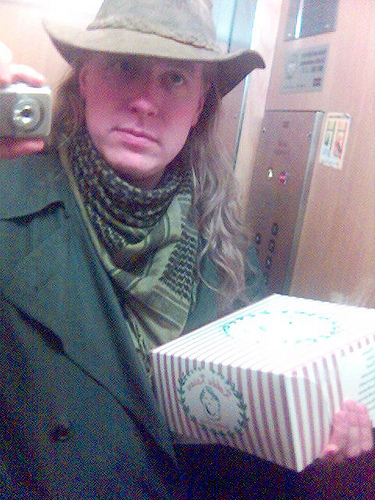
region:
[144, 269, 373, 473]
A pink and white cake box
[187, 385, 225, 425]
Picture of a person on the box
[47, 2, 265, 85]
Gray hat worn by man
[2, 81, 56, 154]
Silver camera held in a hand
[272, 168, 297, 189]
Red button on elevator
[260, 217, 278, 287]
Row of black buttons on elevator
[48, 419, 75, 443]
A round button on jacket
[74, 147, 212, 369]
Black and gray scarf around neck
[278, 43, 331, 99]
Silver plaque on wall with black letters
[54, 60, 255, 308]
Man has long blond hair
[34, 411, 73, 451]
the button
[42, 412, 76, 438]
the button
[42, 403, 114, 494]
the button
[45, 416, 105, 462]
the button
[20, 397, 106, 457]
the button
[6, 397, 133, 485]
the button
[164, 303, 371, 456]
Red, white and green pastry box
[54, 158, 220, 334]
Green and black scarf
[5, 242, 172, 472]
Green coat lapel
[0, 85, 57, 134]
Silver digital camera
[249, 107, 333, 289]
Elevator button panel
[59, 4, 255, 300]
Caucasian man with long hair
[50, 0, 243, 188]
Man wearing a beige hat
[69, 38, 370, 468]
Man with a pastry box in his hand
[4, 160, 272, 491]
Man's green trench coat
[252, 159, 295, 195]
Red emergency button in elevator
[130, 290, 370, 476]
Man holding pastry box in hand.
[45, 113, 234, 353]
Man wearing gray and blue print scarf around neck.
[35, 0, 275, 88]
Man wearing hat with braid trim on head.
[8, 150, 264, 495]
Man wearing gray jacket.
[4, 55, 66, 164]
Man holding camera in hand.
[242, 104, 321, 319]
Silver elevator control panel.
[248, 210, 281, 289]
Floor numbers on black buttons on elevator control panel.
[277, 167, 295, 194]
Red emergency light on elevator control panel.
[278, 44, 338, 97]
Gray sign on wall of elevator.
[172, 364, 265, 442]
White emblem surrounded by green leaves on pastry box.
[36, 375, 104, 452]
the shirt is black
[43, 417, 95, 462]
the shirt is black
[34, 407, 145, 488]
the shirt is black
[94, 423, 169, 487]
the shirt is black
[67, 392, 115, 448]
the shirt is black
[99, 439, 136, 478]
the shirt is black